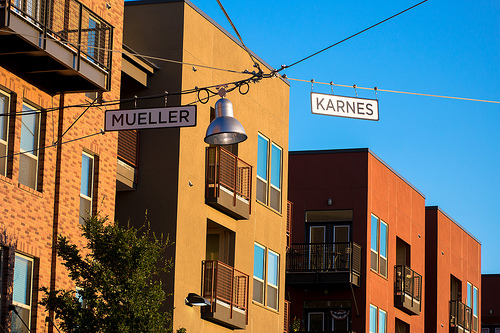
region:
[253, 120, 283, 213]
window on a building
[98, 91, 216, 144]
street sign hanging on electrical wire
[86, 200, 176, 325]
tree near a bulding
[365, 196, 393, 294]
window on a building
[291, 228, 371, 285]
patio on a bulding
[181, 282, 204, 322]
outdoor light o a building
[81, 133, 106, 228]
window on a bulding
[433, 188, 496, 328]
tall orange building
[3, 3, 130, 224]
tall brick building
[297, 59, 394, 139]
street sign on a wire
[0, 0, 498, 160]
The wires are in the middle of the street.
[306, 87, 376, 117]
A sign showing the street Karnes.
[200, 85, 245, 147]
A lamp in the middle of the street.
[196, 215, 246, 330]
One of the balconies of a building.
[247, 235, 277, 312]
One of the windows of a building.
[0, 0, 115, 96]
A very large balcony at the top floor.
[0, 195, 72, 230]
The red and yellow bricks of the building.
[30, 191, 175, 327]
A large tree is outside near the buildings.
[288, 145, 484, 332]
Two red buildings are in the front.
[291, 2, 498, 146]
The big blue sky is up above.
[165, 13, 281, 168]
road light is hanging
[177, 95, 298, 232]
road light is hanging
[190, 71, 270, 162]
road light is hanging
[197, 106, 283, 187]
road light is hanging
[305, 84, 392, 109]
sign is white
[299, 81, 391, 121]
writing on sign is black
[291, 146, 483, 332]
buildings are dark orange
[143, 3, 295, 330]
building is light brown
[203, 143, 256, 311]
building has orange balconies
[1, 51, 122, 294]
building is orange brick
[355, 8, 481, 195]
sky is blue and cloudless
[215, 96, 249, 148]
silver light hanging next to sign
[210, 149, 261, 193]
rail on balcony is orange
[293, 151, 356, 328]
wall of building in shadow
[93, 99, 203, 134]
black and white street signs hanging from black wire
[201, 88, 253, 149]
metal street light hanging from black cord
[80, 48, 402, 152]
two black and white street signs and one metal light hanging from black wire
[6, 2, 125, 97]
brown balcony on front of brick building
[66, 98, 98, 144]
red brick on front of building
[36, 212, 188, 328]
tall green tree in front of brick building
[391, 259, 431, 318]
balcony on front of red building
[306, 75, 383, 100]
four metal hooks connecting street sign to cord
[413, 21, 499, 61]
oatch of clear blue sky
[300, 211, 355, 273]
two doors leading to balcony on side of building